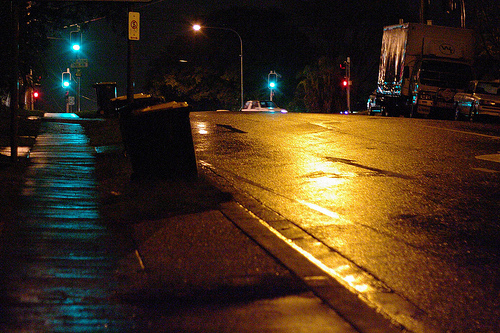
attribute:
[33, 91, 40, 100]
light — red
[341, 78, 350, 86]
light — red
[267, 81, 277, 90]
light — green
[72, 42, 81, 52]
light — bright, green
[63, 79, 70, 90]
light — green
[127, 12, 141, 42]
sign — white, red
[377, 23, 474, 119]
truck — big, white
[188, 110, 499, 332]
street — wet, black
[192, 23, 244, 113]
streetlight — on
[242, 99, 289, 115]
car — white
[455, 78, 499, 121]
car — parked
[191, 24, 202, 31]
light — bright, on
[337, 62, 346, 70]
signal — red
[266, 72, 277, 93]
signal — green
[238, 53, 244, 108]
pole — grey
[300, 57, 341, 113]
tree — green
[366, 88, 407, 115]
car — parked